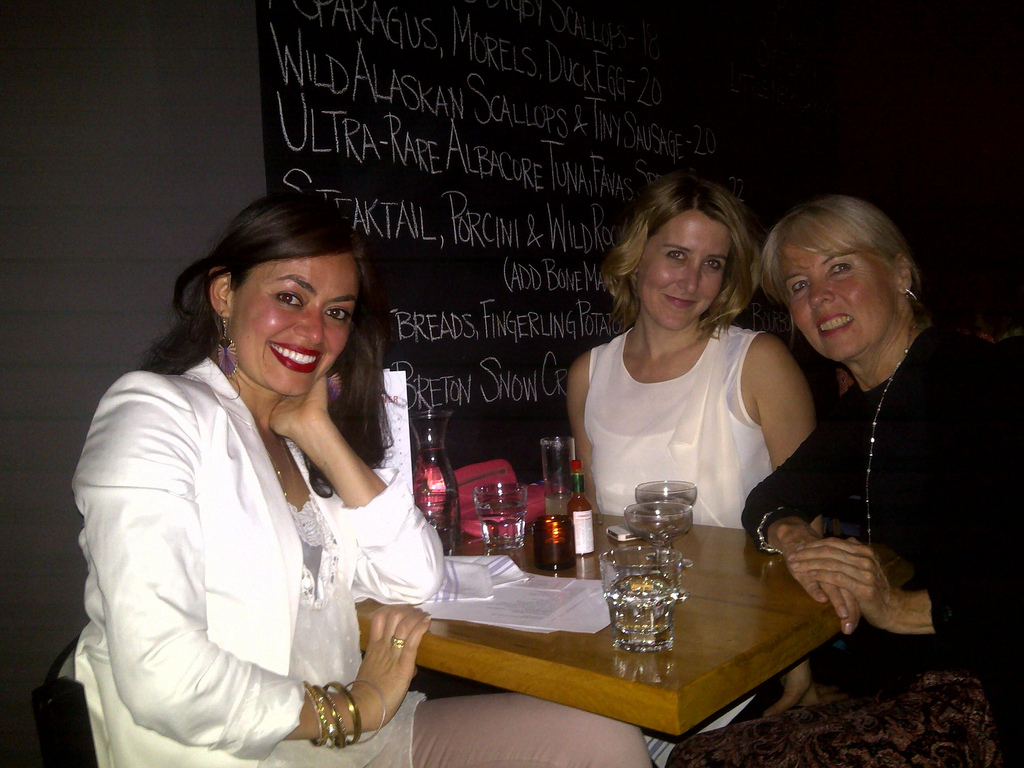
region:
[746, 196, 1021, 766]
Woman wearing black sweater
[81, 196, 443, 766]
Woman wearing a white blazer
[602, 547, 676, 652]
Glass of water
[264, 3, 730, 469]
Blackboard with menu on it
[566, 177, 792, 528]
Woman wearing white blouse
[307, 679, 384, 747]
gold bangle bracelets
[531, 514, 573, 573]
Amber jar with a lite candle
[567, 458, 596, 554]
Jar of Tabasco sauce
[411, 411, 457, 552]
Carafe of water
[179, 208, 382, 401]
the head of a woman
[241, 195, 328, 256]
the brown hair of a woman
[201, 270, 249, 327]
the ear of a woman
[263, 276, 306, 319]
the eye of a woman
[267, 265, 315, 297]
the eyebrow of a woman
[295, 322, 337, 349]
the nose of a woman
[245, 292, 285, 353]
the cheek of a woman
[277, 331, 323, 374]
the mouth of a woman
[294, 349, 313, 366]
the teeth of a woman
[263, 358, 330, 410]
the chin of a woman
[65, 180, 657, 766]
Woman has red lipstick on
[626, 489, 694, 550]
Martini glass on the table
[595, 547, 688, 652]
Glass of water on the table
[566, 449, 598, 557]
Tabasco bottle on the table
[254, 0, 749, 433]
Chalkboard behind a woman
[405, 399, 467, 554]
Glass carafe on the table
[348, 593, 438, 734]
Hand clasping the table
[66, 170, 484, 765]
Woman wearing white shirt and jacket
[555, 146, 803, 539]
Blonde woman in white sleeveless shirt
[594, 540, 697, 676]
Glass on table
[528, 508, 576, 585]
Candle sitting on table in restaurant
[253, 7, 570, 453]
Specials list on chalkboard on wall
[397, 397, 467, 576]
Empty decanter sitting on table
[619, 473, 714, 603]
Wine glasses sitting on table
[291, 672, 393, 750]
Gold bracelets on woman's wrist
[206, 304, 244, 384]
Long dangling purple earring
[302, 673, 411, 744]
A woman is wearing several bracelets on her wrist.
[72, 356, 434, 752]
A woman is wearing a white jacket and a white shirt.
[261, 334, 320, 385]
The woman has red lipstick on her lips.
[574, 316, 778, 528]
A woman is wearing a white sleeveless shirt.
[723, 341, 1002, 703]
A woman is wearing a black sweater.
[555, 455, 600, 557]
A bottle of red hot sauce is on the table.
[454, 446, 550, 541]
A womans pink purse is on the table.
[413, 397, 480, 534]
A clear glass vase is on the table.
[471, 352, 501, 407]
A letter on a sign.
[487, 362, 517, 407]
A letter on a sign.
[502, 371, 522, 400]
A letter on a sign.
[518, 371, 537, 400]
A letter on a sign.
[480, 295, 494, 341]
A letter on a sign.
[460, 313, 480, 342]
A letter on a sign.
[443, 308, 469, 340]
A letter on a sign.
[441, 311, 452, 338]
A letter on a sign.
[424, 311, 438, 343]
A letter on a sign.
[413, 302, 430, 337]
A letter on a sign.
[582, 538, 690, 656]
A clear glass on the table.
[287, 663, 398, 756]
The woman is wearing a few bracelets on her wrist.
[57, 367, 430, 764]
The woman is wearing a white jacket and white shirt.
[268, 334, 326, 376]
The woman has bright red lipstick on.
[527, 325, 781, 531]
The woman is wearing a white shirt.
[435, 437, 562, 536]
A pink purse is on the table.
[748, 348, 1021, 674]
The woman is wearing a black sweater.